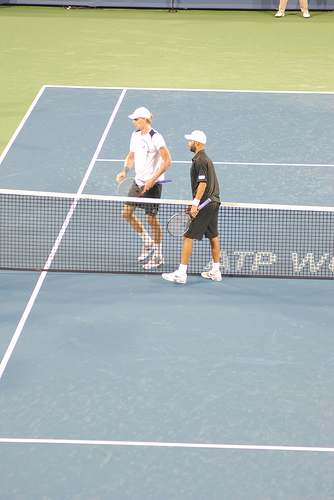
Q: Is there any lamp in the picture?
A: No, there are no lamps.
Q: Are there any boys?
A: No, there are no boys.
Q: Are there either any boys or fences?
A: No, there are no boys or fences.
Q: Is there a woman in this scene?
A: No, there are no women.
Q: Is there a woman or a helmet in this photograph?
A: No, there are no women or helmets.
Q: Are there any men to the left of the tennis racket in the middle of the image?
A: Yes, there is a man to the left of the racket.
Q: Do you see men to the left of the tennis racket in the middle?
A: Yes, there is a man to the left of the racket.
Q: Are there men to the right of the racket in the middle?
A: No, the man is to the left of the tennis racket.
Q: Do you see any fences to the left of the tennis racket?
A: No, there is a man to the left of the tennis racket.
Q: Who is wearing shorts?
A: The man is wearing shorts.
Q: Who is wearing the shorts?
A: The man is wearing shorts.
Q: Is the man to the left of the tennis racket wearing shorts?
A: Yes, the man is wearing shorts.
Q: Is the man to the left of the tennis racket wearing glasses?
A: No, the man is wearing shorts.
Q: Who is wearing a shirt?
A: The man is wearing a shirt.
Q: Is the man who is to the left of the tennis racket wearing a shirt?
A: Yes, the man is wearing a shirt.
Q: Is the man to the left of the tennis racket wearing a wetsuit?
A: No, the man is wearing a shirt.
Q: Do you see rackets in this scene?
A: Yes, there is a racket.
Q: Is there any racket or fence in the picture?
A: Yes, there is a racket.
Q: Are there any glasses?
A: No, there are no glasses.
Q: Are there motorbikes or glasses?
A: No, there are no glasses or motorbikes.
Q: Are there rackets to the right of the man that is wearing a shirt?
A: Yes, there is a racket to the right of the man.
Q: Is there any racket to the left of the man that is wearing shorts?
A: No, the racket is to the right of the man.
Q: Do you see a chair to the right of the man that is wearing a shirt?
A: No, there is a racket to the right of the man.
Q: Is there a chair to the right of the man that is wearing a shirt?
A: No, there is a racket to the right of the man.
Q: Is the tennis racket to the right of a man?
A: Yes, the tennis racket is to the right of a man.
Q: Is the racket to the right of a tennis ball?
A: No, the racket is to the right of a man.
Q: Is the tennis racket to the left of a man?
A: No, the tennis racket is to the right of a man.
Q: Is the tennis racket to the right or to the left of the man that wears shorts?
A: The tennis racket is to the right of the man.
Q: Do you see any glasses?
A: No, there are no glasses.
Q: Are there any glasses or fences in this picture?
A: No, there are no glasses or fences.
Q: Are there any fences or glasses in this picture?
A: No, there are no glasses or fences.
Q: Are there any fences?
A: No, there are no fences.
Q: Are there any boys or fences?
A: No, there are no fences or boys.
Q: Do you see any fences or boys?
A: No, there are no fences or boys.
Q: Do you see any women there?
A: No, there are no women.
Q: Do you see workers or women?
A: No, there are no women or workers.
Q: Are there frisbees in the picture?
A: No, there are no frisbees.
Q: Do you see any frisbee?
A: No, there are no frisbees.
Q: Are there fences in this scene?
A: No, there are no fences.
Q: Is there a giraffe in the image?
A: No, there are no giraffes.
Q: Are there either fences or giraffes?
A: No, there are no giraffes or fences.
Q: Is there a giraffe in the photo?
A: No, there are no giraffes.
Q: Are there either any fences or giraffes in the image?
A: No, there are no giraffes or fences.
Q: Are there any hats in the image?
A: Yes, there is a hat.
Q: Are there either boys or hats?
A: Yes, there is a hat.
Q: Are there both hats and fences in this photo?
A: No, there is a hat but no fences.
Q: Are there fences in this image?
A: No, there are no fences.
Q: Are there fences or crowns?
A: No, there are no fences or crowns.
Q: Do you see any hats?
A: Yes, there is a hat.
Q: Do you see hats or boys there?
A: Yes, there is a hat.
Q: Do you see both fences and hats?
A: No, there is a hat but no fences.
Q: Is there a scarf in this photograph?
A: No, there are no scarves.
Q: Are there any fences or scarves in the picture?
A: No, there are no scarves or fences.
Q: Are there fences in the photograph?
A: No, there are no fences.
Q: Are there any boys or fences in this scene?
A: No, there are no fences or boys.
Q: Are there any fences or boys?
A: No, there are no fences or boys.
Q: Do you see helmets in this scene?
A: No, there are no helmets.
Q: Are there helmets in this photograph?
A: No, there are no helmets.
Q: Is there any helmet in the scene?
A: No, there are no helmets.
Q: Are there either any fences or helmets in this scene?
A: No, there are no helmets or fences.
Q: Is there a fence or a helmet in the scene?
A: No, there are no helmets or fences.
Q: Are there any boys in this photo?
A: No, there are no boys.